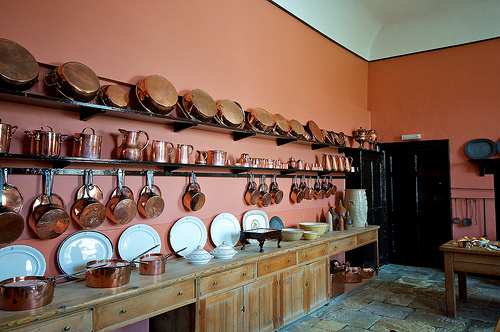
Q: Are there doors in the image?
A: Yes, there is a door.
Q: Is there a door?
A: Yes, there is a door.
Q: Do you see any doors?
A: Yes, there is a door.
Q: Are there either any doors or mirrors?
A: Yes, there is a door.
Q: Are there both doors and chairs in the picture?
A: No, there is a door but no chairs.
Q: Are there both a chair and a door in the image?
A: No, there is a door but no chairs.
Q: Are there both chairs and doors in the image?
A: No, there is a door but no chairs.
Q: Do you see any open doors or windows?
A: Yes, there is an open door.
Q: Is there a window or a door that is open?
A: Yes, the door is open.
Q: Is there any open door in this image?
A: Yes, there is an open door.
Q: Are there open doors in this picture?
A: Yes, there is an open door.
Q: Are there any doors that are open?
A: Yes, there is a door that is open.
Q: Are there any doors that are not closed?
A: Yes, there is a open door.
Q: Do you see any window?
A: No, there are no windows.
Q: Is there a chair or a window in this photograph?
A: No, there are no windows or chairs.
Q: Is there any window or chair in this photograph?
A: No, there are no windows or chairs.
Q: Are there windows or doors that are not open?
A: No, there is a door but it is open.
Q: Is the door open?
A: Yes, the door is open.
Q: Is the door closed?
A: No, the door is open.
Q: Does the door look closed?
A: No, the door is open.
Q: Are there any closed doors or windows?
A: No, there is a door but it is open.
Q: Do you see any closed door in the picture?
A: No, there is a door but it is open.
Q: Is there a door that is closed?
A: No, there is a door but it is open.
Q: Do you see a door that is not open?
A: No, there is a door but it is open.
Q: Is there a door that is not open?
A: No, there is a door but it is open.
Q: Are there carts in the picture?
A: No, there are no carts.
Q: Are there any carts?
A: No, there are no carts.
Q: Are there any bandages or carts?
A: No, there are no carts or bandages.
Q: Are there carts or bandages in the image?
A: No, there are no carts or bandages.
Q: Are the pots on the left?
A: Yes, the pots are on the left of the image.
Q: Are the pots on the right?
A: No, the pots are on the left of the image.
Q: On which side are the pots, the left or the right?
A: The pots are on the left of the image.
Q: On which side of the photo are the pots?
A: The pots are on the left of the image.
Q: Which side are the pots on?
A: The pots are on the left of the image.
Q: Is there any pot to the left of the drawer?
A: Yes, there are pots to the left of the drawer.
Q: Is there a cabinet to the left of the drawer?
A: No, there are pots to the left of the drawer.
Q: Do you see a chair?
A: No, there are no chairs.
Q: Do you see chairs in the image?
A: No, there are no chairs.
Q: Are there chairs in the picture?
A: No, there are no chairs.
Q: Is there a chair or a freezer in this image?
A: No, there are no chairs or refrigerators.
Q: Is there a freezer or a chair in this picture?
A: No, there are no chairs or refrigerators.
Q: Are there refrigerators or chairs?
A: No, there are no chairs or refrigerators.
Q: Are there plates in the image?
A: Yes, there is a plate.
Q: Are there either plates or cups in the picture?
A: Yes, there is a plate.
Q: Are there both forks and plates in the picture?
A: No, there is a plate but no forks.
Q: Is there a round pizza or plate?
A: Yes, there is a round plate.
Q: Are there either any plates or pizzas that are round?
A: Yes, the plate is round.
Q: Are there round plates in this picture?
A: Yes, there is a round plate.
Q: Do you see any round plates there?
A: Yes, there is a round plate.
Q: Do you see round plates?
A: Yes, there is a round plate.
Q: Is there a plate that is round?
A: Yes, there is a plate that is round.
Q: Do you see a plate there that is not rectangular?
A: Yes, there is a round plate.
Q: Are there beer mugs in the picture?
A: No, there are no beer mugs.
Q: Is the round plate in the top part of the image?
A: No, the plate is in the bottom of the image.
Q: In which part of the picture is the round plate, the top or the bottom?
A: The plate is in the bottom of the image.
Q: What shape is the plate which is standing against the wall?
A: The plate is round.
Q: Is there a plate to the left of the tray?
A: Yes, there is a plate to the left of the tray.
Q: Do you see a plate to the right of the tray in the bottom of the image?
A: No, the plate is to the left of the tray.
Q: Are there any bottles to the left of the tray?
A: No, there is a plate to the left of the tray.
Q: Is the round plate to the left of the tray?
A: Yes, the plate is to the left of the tray.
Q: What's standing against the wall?
A: The plate is standing against the wall.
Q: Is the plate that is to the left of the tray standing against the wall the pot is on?
A: Yes, the plate is standing against the wall.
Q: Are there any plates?
A: Yes, there is a plate.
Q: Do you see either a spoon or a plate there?
A: Yes, there is a plate.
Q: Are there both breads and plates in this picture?
A: No, there is a plate but no breads.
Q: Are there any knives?
A: No, there are no knives.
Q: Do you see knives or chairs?
A: No, there are no knives or chairs.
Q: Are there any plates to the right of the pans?
A: Yes, there is a plate to the right of the pans.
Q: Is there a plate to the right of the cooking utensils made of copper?
A: Yes, there is a plate to the right of the pans.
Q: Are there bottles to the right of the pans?
A: No, there is a plate to the right of the pans.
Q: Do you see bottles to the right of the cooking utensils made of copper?
A: No, there is a plate to the right of the pans.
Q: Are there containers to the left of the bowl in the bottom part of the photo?
A: No, there is a plate to the left of the bowl.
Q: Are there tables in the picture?
A: Yes, there is a table.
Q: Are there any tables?
A: Yes, there is a table.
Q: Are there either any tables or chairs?
A: Yes, there is a table.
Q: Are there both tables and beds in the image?
A: No, there is a table but no beds.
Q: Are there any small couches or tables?
A: Yes, there is a small table.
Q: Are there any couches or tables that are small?
A: Yes, the table is small.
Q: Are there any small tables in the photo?
A: Yes, there is a small table.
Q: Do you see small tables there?
A: Yes, there is a small table.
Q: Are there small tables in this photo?
A: Yes, there is a small table.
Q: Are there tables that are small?
A: Yes, there is a table that is small.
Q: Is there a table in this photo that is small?
A: Yes, there is a table that is small.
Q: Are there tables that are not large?
A: Yes, there is a small table.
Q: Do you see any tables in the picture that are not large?
A: Yes, there is a small table.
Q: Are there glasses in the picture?
A: No, there are no glasses.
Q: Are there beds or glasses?
A: No, there are no glasses or beds.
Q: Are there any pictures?
A: No, there are no pictures.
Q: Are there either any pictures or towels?
A: No, there are no pictures or towels.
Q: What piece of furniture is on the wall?
A: The piece of furniture is a shelf.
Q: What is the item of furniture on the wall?
A: The piece of furniture is a shelf.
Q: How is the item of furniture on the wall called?
A: The piece of furniture is a shelf.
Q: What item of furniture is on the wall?
A: The piece of furniture is a shelf.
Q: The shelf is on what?
A: The shelf is on the wall.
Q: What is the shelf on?
A: The shelf is on the wall.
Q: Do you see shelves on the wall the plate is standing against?
A: Yes, there is a shelf on the wall.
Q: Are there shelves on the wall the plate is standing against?
A: Yes, there is a shelf on the wall.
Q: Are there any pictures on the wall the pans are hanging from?
A: No, there is a shelf on the wall.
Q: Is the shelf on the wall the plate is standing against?
A: Yes, the shelf is on the wall.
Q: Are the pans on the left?
A: Yes, the pans are on the left of the image.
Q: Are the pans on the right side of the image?
A: No, the pans are on the left of the image.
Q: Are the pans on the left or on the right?
A: The pans are on the left of the image.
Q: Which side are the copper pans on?
A: The pans are on the left of the image.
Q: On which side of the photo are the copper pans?
A: The pans are on the left of the image.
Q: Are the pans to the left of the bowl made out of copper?
A: Yes, the pans are made of copper.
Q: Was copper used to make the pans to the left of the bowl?
A: Yes, the pans are made of copper.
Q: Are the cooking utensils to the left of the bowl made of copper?
A: Yes, the pans are made of copper.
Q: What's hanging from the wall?
A: The pans are hanging from the wall.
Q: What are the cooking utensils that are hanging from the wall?
A: The cooking utensils are pans.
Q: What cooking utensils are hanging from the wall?
A: The cooking utensils are pans.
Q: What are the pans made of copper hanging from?
A: The pans are hanging from the wall.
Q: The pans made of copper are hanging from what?
A: The pans are hanging from the wall.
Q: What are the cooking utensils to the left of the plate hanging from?
A: The pans are hanging from the wall.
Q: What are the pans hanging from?
A: The pans are hanging from the wall.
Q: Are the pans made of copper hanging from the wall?
A: Yes, the pans are hanging from the wall.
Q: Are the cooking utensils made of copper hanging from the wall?
A: Yes, the pans are hanging from the wall.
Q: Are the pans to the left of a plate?
A: Yes, the pans are to the left of a plate.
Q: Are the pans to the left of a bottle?
A: No, the pans are to the left of a plate.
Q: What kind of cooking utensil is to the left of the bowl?
A: The cooking utensils are pans.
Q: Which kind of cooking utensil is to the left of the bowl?
A: The cooking utensils are pans.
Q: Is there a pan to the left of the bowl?
A: Yes, there are pans to the left of the bowl.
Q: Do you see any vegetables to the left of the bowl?
A: No, there are pans to the left of the bowl.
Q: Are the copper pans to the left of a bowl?
A: Yes, the pans are to the left of a bowl.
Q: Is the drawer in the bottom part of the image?
A: Yes, the drawer is in the bottom of the image.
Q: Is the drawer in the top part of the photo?
A: No, the drawer is in the bottom of the image.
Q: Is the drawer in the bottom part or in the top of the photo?
A: The drawer is in the bottom of the image.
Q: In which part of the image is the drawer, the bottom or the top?
A: The drawer is in the bottom of the image.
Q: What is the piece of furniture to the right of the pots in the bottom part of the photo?
A: The piece of furniture is a drawer.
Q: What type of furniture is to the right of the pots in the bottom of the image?
A: The piece of furniture is a drawer.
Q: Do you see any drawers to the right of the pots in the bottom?
A: Yes, there is a drawer to the right of the pots.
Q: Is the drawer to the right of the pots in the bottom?
A: Yes, the drawer is to the right of the pots.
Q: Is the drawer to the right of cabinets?
A: No, the drawer is to the right of the pots.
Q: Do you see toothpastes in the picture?
A: No, there are no toothpastes.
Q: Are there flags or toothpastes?
A: No, there are no toothpastes or flags.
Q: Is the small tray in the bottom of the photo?
A: Yes, the tray is in the bottom of the image.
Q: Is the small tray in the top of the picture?
A: No, the tray is in the bottom of the image.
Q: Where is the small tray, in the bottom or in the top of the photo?
A: The tray is in the bottom of the image.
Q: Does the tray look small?
A: Yes, the tray is small.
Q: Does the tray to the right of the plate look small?
A: Yes, the tray is small.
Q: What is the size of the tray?
A: The tray is small.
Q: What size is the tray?
A: The tray is small.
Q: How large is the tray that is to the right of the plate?
A: The tray is small.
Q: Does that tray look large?
A: No, the tray is small.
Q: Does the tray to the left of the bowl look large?
A: No, the tray is small.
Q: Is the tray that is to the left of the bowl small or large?
A: The tray is small.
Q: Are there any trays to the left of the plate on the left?
A: No, the tray is to the right of the plate.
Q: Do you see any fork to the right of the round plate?
A: No, there is a tray to the right of the plate.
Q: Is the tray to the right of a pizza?
A: No, the tray is to the right of the plate.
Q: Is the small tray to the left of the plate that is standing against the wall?
A: No, the tray is to the right of the plate.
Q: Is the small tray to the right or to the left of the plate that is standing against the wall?
A: The tray is to the right of the plate.